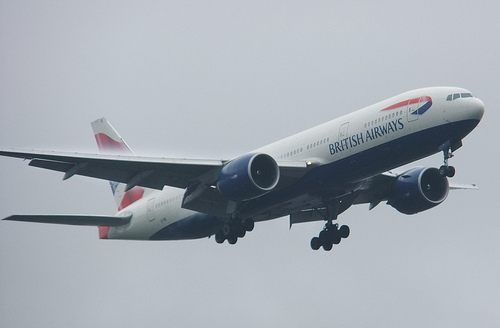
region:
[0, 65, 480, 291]
the plane is in the air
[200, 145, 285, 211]
the engine is blue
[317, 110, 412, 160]
the letters are blue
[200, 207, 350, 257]
the wheels are out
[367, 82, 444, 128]
a curve on the side of the plane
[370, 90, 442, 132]
the curve is red and blue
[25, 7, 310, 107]
the sky is overcast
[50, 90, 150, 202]
the tail of the plane is red, white, and blue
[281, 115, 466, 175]
the bottom of the plane is blue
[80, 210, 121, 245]
the back tip of the plane is red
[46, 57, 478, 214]
Airplane on take off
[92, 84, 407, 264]
Airplane on take off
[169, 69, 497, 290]
Airplane on take off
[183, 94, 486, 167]
Airplane on take off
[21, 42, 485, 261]
Airliner flying in the sky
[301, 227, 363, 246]
landing gear on the plane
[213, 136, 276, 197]
engine on a plane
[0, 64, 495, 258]
large plane in the air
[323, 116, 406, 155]
words "British Airways" on the plane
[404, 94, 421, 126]
front door on the plane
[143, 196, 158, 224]
rear door on the plane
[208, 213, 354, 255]
wheels of the landing gear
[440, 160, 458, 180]
front wheel of the landing gear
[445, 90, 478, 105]
windows of the cockpit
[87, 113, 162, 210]
tail of the plane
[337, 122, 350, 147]
middle door on the right side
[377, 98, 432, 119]
red and blue logo near the front of the plane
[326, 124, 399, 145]
writing on the plane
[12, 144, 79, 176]
wing on the plane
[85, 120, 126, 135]
tail of the plane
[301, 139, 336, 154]
windows on the train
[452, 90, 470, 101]
the windshield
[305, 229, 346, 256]
the wheels on the plane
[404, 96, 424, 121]
door on the plane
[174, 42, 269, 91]
the sky is clear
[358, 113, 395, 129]
the plane has windows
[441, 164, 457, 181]
front wheel